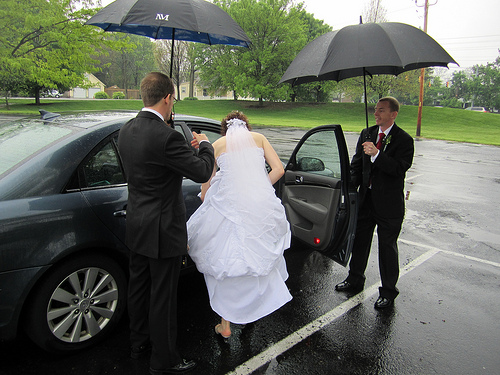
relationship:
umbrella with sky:
[82, 0, 247, 81] [118, 18, 221, 58]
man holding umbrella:
[330, 57, 448, 298] [281, 9, 460, 94]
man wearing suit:
[330, 57, 448, 298] [349, 122, 433, 309]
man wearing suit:
[92, 29, 234, 330] [85, 120, 240, 282]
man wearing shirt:
[333, 95, 413, 310] [363, 122, 402, 155]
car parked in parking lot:
[8, 102, 396, 344] [266, 118, 497, 374]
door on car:
[241, 104, 369, 286] [3, 108, 375, 338]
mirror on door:
[297, 160, 322, 170] [241, 104, 369, 286]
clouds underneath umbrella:
[143, 25, 230, 46] [276, 12, 454, 103]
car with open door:
[3, 108, 375, 338] [274, 167, 353, 263]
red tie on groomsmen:
[371, 130, 388, 147] [125, 54, 427, 344]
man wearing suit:
[314, 86, 421, 328] [349, 122, 433, 309]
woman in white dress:
[186, 109, 293, 342] [187, 146, 292, 326]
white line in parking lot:
[172, 255, 477, 372] [0, 112, 499, 372]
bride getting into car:
[184, 116, 293, 346] [8, 102, 396, 344]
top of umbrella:
[276, 20, 458, 85] [276, 12, 454, 103]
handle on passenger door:
[109, 205, 131, 221] [75, 115, 192, 293]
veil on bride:
[223, 116, 275, 223] [184, 116, 293, 346]